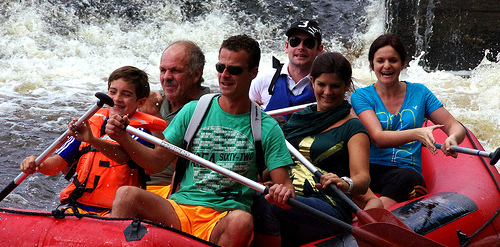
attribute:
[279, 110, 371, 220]
shirt — green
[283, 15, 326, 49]
hat — black, white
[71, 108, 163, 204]
life vest — orange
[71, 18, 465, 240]
group of people — rafting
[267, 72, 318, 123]
life jacket — blue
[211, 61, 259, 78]
sunglasses — black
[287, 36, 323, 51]
sunglasses — black